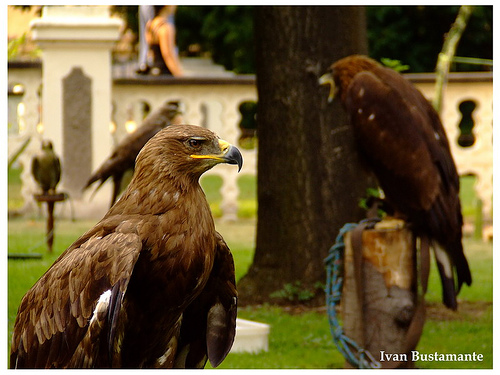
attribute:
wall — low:
[105, 65, 275, 232]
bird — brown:
[308, 46, 483, 318]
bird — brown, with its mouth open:
[316, 46, 472, 297]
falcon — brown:
[43, 109, 259, 373]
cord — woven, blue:
[297, 223, 370, 373]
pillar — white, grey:
[32, 8, 132, 231]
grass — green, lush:
[18, 230, 488, 369]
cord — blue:
[319, 219, 366, 360]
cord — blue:
[320, 219, 360, 358]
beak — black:
[222, 142, 245, 171]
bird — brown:
[42, 117, 254, 367]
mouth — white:
[314, 73, 337, 103]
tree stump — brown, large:
[333, 219, 421, 373]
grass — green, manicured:
[9, 210, 499, 361]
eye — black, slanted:
[178, 133, 216, 152]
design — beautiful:
[450, 88, 485, 156]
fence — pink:
[218, 76, 498, 221]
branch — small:
[270, 281, 298, 315]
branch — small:
[303, 279, 316, 300]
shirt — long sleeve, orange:
[148, 20, 172, 66]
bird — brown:
[17, 109, 261, 373]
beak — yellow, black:
[204, 134, 245, 177]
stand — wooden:
[31, 188, 72, 243]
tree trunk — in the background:
[245, 20, 379, 314]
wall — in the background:
[11, 11, 481, 128]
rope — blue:
[310, 205, 376, 364]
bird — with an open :
[296, 58, 347, 113]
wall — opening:
[450, 87, 481, 160]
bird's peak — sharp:
[163, 121, 254, 188]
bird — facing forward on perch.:
[24, 128, 65, 253]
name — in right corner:
[374, 344, 484, 372]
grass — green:
[264, 255, 482, 359]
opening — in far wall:
[229, 97, 260, 158]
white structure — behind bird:
[10, 7, 481, 202]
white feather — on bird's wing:
[76, 286, 113, 332]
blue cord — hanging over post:
[323, 222, 389, 368]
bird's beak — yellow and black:
[188, 137, 243, 175]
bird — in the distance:
[26, 136, 68, 197]